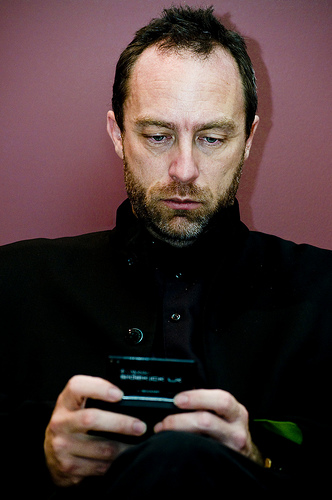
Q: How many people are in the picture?
A: One.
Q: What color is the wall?
A: Purple.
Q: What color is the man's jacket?
A: Black.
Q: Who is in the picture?
A: A man.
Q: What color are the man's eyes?
A: Blue.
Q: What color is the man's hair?
A: Brown.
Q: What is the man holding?
A: A cellphone.